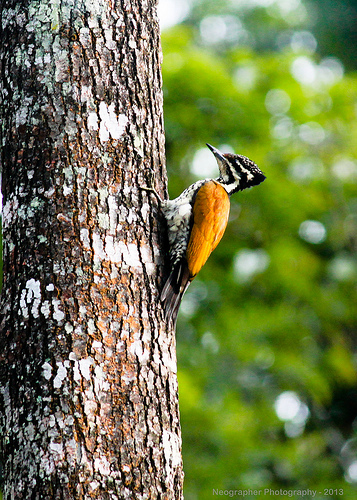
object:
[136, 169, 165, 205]
leg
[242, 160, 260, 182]
stripes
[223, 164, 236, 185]
stripes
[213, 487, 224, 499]
white print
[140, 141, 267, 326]
bird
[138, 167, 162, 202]
feet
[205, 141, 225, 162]
beak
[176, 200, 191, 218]
feathers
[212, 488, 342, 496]
letter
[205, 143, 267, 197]
head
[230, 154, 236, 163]
eye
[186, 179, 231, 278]
wing